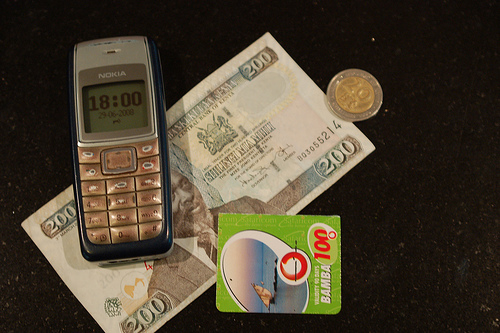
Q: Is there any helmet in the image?
A: No, there are no helmets.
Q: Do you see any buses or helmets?
A: No, there are no helmets or buses.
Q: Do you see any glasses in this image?
A: No, there are no glasses.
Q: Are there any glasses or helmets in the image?
A: No, there are no glasses or helmets.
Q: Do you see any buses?
A: No, there are no buses.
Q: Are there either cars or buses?
A: No, there are no buses or cars.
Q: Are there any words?
A: Yes, there are words.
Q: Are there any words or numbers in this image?
A: Yes, there are words.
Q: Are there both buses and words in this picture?
A: No, there are words but no buses.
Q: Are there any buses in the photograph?
A: No, there are no buses.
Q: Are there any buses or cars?
A: No, there are no buses or cars.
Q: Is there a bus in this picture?
A: No, there are no buses.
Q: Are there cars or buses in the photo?
A: No, there are no buses or cars.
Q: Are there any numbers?
A: Yes, there are numbers.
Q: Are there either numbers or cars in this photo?
A: Yes, there are numbers.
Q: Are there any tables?
A: Yes, there is a table.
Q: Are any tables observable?
A: Yes, there is a table.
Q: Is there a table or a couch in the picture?
A: Yes, there is a table.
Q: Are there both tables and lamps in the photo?
A: No, there is a table but no lamps.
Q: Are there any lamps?
A: No, there are no lamps.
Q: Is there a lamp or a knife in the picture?
A: No, there are no lamps or knives.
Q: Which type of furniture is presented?
A: The furniture is a table.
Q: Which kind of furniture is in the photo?
A: The furniture is a table.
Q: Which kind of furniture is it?
A: The piece of furniture is a table.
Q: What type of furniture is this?
A: This is a table.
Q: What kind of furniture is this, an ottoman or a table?
A: This is a table.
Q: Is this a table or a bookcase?
A: This is a table.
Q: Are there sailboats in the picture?
A: Yes, there is a sailboat.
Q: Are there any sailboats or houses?
A: Yes, there is a sailboat.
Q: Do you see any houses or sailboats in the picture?
A: Yes, there is a sailboat.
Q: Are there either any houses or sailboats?
A: Yes, there is a sailboat.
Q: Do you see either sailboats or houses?
A: Yes, there is a sailboat.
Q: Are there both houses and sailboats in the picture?
A: No, there is a sailboat but no houses.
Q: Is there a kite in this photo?
A: No, there are no kites.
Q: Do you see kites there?
A: No, there are no kites.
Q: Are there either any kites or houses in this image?
A: No, there are no kites or houses.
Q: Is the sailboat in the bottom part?
A: Yes, the sailboat is in the bottom of the image.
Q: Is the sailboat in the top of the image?
A: No, the sailboat is in the bottom of the image.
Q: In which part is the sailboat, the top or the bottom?
A: The sailboat is in the bottom of the image.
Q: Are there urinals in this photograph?
A: No, there are no urinals.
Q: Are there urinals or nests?
A: No, there are no urinals or nests.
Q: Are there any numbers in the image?
A: Yes, there are numbers.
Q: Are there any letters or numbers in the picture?
A: Yes, there are numbers.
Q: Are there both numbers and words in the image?
A: Yes, there are both numbers and words.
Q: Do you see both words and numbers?
A: Yes, there are both numbers and words.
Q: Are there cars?
A: No, there are no cars.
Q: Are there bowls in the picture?
A: No, there are no bowls.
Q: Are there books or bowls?
A: No, there are no bowls or books.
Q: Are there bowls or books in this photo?
A: No, there are no bowls or books.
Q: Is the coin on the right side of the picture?
A: Yes, the coin is on the right of the image.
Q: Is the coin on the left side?
A: No, the coin is on the right of the image.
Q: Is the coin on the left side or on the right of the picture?
A: The coin is on the right of the image.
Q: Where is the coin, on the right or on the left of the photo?
A: The coin is on the right of the image.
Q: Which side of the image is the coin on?
A: The coin is on the right of the image.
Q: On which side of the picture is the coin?
A: The coin is on the right of the image.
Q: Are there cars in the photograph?
A: No, there are no cars.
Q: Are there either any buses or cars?
A: No, there are no cars or buses.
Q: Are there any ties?
A: Yes, there is a tie.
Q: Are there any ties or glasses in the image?
A: Yes, there is a tie.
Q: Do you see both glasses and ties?
A: No, there is a tie but no glasses.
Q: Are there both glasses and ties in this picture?
A: No, there is a tie but no glasses.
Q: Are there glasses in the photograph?
A: No, there are no glasses.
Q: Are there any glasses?
A: No, there are no glasses.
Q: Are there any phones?
A: Yes, there is a phone.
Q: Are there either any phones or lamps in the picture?
A: Yes, there is a phone.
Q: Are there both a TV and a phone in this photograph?
A: No, there is a phone but no televisions.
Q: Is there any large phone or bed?
A: Yes, there is a large phone.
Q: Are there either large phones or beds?
A: Yes, there is a large phone.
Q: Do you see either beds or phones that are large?
A: Yes, the phone is large.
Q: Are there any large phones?
A: Yes, there is a large phone.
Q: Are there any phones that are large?
A: Yes, there is a large phone.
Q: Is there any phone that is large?
A: Yes, there is a phone that is large.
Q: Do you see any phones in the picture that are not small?
A: Yes, there is a large phone.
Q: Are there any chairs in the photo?
A: No, there are no chairs.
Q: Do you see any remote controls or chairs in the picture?
A: No, there are no chairs or remote controls.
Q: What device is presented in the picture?
A: The device is a phone.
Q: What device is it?
A: The device is a phone.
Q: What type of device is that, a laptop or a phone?
A: That is a phone.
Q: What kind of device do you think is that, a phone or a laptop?
A: That is a phone.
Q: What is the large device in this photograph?
A: The device is a phone.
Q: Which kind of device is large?
A: The device is a phone.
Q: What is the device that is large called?
A: The device is a phone.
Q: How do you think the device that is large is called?
A: The device is a phone.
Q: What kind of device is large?
A: The device is a phone.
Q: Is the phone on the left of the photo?
A: Yes, the phone is on the left of the image.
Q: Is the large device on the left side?
A: Yes, the phone is on the left of the image.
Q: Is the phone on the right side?
A: No, the phone is on the left of the image.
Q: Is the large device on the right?
A: No, the phone is on the left of the image.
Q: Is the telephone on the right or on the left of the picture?
A: The telephone is on the left of the image.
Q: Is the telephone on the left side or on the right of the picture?
A: The telephone is on the left of the image.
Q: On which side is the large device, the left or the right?
A: The telephone is on the left of the image.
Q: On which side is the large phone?
A: The telephone is on the left of the image.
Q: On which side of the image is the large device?
A: The telephone is on the left of the image.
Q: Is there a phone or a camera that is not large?
A: No, there is a phone but it is large.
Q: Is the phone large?
A: Yes, the phone is large.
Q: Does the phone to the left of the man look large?
A: Yes, the telephone is large.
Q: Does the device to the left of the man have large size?
A: Yes, the telephone is large.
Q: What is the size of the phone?
A: The phone is large.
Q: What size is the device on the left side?
A: The phone is large.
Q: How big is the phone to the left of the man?
A: The phone is large.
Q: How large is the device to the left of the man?
A: The phone is large.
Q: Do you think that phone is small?
A: No, the phone is large.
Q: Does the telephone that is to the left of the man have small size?
A: No, the phone is large.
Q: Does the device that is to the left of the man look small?
A: No, the phone is large.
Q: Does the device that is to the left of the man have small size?
A: No, the phone is large.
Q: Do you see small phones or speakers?
A: No, there is a phone but it is large.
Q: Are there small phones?
A: No, there is a phone but it is large.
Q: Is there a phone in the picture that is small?
A: No, there is a phone but it is large.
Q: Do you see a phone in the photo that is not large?
A: No, there is a phone but it is large.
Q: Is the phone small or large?
A: The phone is large.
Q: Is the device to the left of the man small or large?
A: The phone is large.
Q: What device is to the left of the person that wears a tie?
A: The device is a phone.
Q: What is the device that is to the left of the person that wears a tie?
A: The device is a phone.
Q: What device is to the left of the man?
A: The device is a phone.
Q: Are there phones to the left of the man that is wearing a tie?
A: Yes, there is a phone to the left of the man.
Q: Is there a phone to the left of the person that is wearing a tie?
A: Yes, there is a phone to the left of the man.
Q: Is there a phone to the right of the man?
A: No, the phone is to the left of the man.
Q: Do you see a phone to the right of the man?
A: No, the phone is to the left of the man.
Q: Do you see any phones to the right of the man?
A: No, the phone is to the left of the man.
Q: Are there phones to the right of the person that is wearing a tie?
A: No, the phone is to the left of the man.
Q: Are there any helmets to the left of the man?
A: No, there is a phone to the left of the man.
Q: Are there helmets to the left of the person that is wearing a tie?
A: No, there is a phone to the left of the man.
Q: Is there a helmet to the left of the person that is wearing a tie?
A: No, there is a phone to the left of the man.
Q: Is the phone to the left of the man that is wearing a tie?
A: Yes, the phone is to the left of the man.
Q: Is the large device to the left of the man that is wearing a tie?
A: Yes, the phone is to the left of the man.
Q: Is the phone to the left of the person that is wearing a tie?
A: Yes, the phone is to the left of the man.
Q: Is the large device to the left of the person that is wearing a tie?
A: Yes, the phone is to the left of the man.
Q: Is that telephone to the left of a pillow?
A: No, the telephone is to the left of the man.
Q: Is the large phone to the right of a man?
A: No, the phone is to the left of a man.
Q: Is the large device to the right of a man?
A: No, the phone is to the left of a man.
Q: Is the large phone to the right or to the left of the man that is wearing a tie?
A: The phone is to the left of the man.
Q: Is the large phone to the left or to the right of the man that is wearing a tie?
A: The phone is to the left of the man.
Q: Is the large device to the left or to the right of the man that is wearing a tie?
A: The phone is to the left of the man.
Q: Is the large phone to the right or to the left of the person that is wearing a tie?
A: The phone is to the left of the man.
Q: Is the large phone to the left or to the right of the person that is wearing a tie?
A: The phone is to the left of the man.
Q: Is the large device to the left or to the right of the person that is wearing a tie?
A: The phone is to the left of the man.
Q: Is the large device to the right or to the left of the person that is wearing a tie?
A: The phone is to the left of the man.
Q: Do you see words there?
A: Yes, there are words.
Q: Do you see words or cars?
A: Yes, there are words.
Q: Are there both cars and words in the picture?
A: No, there are words but no cars.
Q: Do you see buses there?
A: No, there are no buses.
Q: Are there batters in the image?
A: No, there are no batters.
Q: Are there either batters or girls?
A: No, there are no batters or girls.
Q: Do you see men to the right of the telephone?
A: Yes, there is a man to the right of the telephone.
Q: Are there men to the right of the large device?
A: Yes, there is a man to the right of the telephone.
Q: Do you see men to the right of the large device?
A: Yes, there is a man to the right of the telephone.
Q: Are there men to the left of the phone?
A: No, the man is to the right of the phone.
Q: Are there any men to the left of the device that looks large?
A: No, the man is to the right of the phone.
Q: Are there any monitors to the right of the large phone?
A: No, there is a man to the right of the phone.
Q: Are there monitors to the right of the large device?
A: No, there is a man to the right of the phone.